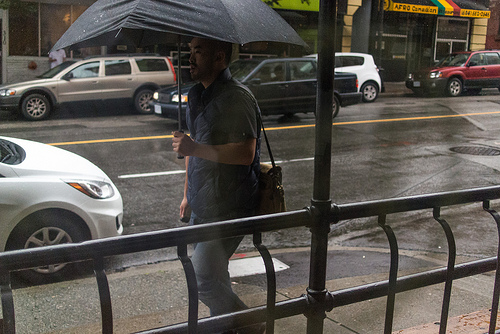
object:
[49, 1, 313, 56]
umbrella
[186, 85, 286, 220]
suitcase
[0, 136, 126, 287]
car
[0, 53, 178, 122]
car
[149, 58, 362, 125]
car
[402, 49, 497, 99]
car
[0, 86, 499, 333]
street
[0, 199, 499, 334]
sidewalk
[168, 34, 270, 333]
man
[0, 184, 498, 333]
fence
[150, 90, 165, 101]
car's lights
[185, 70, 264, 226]
shirt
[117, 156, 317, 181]
lines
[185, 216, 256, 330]
pants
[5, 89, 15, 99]
one headlight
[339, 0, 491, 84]
store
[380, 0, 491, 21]
colorful awning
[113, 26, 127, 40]
broken part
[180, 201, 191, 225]
phone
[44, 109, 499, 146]
line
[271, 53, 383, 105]
vehicles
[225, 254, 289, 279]
lid